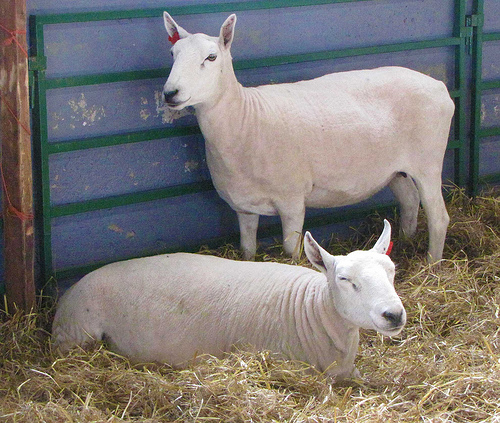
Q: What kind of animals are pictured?
A: Sheep.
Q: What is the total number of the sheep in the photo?
A: 2.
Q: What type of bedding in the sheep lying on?
A: Hay.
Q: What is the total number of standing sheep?
A: 1.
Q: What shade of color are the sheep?
A: White.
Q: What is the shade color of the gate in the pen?
A: Green.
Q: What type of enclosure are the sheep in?
A: Pen.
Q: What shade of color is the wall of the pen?
A: Blue.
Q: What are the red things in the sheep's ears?
A: Tags.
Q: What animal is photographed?
A: Sheep.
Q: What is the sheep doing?
A: Laying down.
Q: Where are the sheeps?
A: Barn.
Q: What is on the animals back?
A: Skin.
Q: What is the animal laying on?
A: Hay.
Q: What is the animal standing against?
A: Fence.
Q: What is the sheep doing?
A: Standing.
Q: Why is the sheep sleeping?
A: Resting.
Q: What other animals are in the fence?
A: Only sheep.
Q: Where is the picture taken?
A: A farm.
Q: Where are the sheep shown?
A: A pen.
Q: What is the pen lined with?
A: Hay.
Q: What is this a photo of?
A: Sheep.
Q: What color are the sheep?
A: White.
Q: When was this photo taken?
A: In the daytime.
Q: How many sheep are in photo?
A: Two.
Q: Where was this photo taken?
A: In a barn.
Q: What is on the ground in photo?
A: Hay.